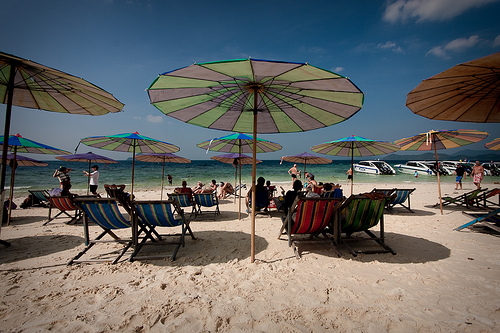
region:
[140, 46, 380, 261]
An umbrella sticking out of the sand.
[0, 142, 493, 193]
A body of water near a beach.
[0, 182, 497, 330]
a sandy beach under a blue sky.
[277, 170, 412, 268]
a lawn chair on a beach.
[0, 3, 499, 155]
a dark blue sky.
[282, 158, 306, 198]
a man standing on a beach.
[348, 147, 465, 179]
shiny metal structure.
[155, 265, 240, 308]
foot prints in the sand.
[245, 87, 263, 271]
a wooden pole under an umbrella.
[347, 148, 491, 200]
a group of boats.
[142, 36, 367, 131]
Red and yellow umbrella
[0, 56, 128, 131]
Red and yellow umbrella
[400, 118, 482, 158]
Red and yellow umbrella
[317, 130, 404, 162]
Red and yellow umbrella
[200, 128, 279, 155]
Red and yellow umbrella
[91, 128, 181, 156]
Red and yellow umbrella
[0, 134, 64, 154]
Red and yellow umbrella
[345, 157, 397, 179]
Boat in the ocean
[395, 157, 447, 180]
Boat in the ocean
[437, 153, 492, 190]
Boat in the ocean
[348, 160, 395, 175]
White boat on water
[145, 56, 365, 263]
Big umbrella stuck in sand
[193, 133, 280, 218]
Big umbrella stuck in sand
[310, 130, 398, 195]
Big umbrella stuck in sand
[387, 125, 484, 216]
Big umbrella stuck in sand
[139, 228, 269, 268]
Shadow of umbrella on sand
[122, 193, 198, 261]
Blue chair next to umbrella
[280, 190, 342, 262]
Red chair next to umbrella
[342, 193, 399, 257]
Green chair next to red chair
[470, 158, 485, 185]
Man in pink and white shorts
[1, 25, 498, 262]
several umbrellas at the beach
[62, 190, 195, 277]
two blue beach chairs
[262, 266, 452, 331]
soft sand at the beach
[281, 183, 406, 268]
a red and green beach chair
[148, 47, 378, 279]
a colorful umbrella in the sand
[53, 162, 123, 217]
two people at the beach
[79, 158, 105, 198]
a woman taking a picture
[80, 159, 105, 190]
a woman wearing a cap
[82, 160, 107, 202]
a woman with a white top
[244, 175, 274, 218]
a man sitting at the beach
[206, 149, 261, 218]
The umbrella is open.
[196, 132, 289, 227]
The umbrella is open.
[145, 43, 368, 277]
The umbrella is open.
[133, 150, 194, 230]
The umbrella is open.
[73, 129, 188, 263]
The umbrella is open.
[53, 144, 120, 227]
The umbrella is open.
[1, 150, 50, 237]
The umbrella is open.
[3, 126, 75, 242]
The umbrella is open.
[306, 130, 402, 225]
The umbrella is open.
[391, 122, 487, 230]
The umbrella is open.